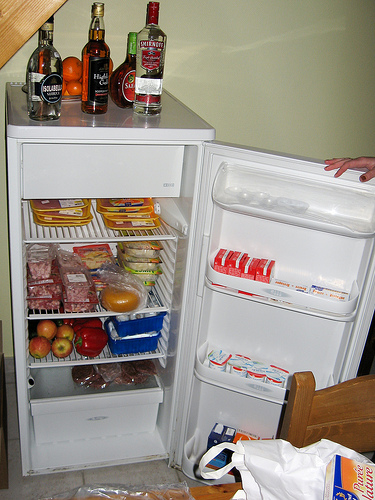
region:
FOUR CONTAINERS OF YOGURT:
[201, 344, 296, 389]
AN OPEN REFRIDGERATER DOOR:
[178, 147, 369, 498]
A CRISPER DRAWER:
[12, 383, 174, 451]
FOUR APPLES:
[20, 320, 74, 359]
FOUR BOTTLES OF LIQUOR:
[19, 1, 189, 125]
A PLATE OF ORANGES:
[18, 50, 98, 106]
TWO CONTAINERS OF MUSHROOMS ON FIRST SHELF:
[103, 305, 163, 360]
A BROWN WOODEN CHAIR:
[270, 360, 370, 459]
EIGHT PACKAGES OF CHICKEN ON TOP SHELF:
[22, 195, 166, 233]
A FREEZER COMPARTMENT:
[20, 138, 191, 202]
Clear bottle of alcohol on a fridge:
[27, 32, 63, 116]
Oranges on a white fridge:
[60, 55, 93, 105]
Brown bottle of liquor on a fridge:
[83, 7, 119, 117]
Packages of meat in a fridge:
[25, 201, 169, 232]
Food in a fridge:
[25, 245, 173, 309]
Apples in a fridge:
[28, 322, 73, 361]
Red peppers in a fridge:
[70, 320, 115, 360]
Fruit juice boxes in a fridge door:
[212, 245, 283, 299]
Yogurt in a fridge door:
[203, 337, 305, 400]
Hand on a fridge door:
[322, 150, 373, 185]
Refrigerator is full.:
[2, 72, 372, 482]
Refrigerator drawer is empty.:
[2, 121, 373, 491]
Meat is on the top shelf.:
[6, 113, 374, 498]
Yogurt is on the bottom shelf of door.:
[170, 137, 373, 477]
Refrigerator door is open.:
[6, 78, 371, 463]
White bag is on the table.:
[72, 436, 374, 498]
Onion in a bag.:
[15, 234, 187, 325]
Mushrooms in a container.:
[106, 312, 166, 355]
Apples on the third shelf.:
[26, 314, 184, 369]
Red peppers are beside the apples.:
[20, 313, 119, 363]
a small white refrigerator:
[5, 81, 370, 476]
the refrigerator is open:
[2, 125, 373, 475]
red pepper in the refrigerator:
[73, 328, 106, 354]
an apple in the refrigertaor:
[29, 337, 49, 360]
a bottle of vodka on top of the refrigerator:
[132, 1, 166, 111]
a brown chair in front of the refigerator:
[283, 369, 374, 451]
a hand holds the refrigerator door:
[325, 151, 374, 184]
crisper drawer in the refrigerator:
[28, 386, 163, 434]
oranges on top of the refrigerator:
[62, 56, 81, 93]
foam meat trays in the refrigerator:
[30, 199, 93, 225]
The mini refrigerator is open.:
[7, 104, 373, 477]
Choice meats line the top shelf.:
[25, 198, 165, 243]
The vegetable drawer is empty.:
[31, 389, 163, 443]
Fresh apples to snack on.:
[28, 318, 80, 363]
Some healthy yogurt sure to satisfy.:
[208, 342, 292, 388]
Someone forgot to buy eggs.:
[218, 176, 312, 222]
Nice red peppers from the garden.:
[69, 315, 111, 362]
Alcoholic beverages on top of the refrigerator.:
[19, 2, 191, 119]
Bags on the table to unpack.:
[190, 429, 374, 498]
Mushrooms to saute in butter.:
[106, 311, 167, 353]